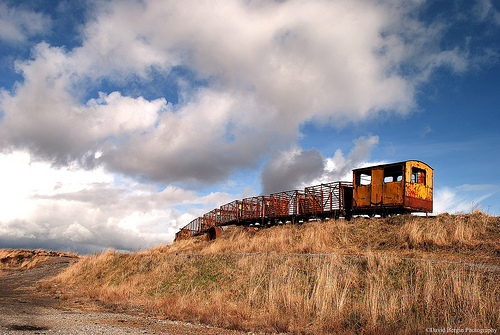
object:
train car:
[337, 157, 438, 218]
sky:
[0, 4, 499, 216]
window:
[381, 165, 404, 183]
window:
[352, 169, 374, 186]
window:
[411, 166, 429, 185]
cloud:
[0, 0, 353, 179]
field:
[71, 216, 496, 334]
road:
[1, 255, 224, 333]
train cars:
[303, 179, 351, 219]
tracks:
[412, 212, 498, 220]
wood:
[175, 227, 187, 241]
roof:
[353, 159, 436, 177]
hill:
[100, 214, 500, 308]